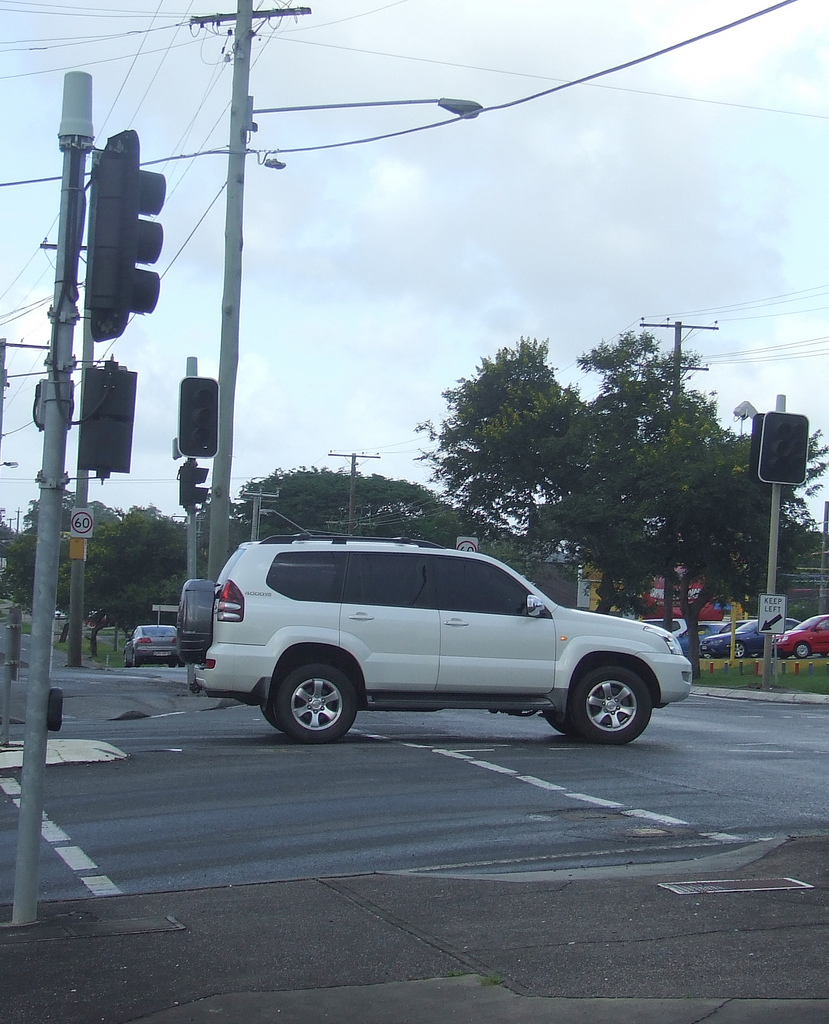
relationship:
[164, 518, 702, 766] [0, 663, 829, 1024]
vehicle at ground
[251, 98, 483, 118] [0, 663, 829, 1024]
light hanging over ground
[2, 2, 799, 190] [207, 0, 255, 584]
wires from pole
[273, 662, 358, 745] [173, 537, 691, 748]
tire on car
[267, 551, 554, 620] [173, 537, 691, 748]
window of car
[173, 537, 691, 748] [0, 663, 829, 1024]
car in middle ground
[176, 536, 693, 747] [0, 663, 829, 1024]
car on ground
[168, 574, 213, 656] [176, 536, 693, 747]
spare tire on car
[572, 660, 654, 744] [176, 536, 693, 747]
tire on car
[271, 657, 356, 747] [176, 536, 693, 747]
tire on car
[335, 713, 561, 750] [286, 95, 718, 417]
shadow under a sky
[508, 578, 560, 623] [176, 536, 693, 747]
view mirror on a car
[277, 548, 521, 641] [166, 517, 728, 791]
window on a suv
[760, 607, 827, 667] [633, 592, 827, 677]
car in a parking lot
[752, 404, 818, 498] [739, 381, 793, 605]
traffic signal on pole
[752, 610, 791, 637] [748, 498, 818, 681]
arrow on pole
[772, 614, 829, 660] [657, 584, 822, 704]
car in parking lot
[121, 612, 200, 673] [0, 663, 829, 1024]
car driving down ground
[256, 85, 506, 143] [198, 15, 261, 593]
light hanging from pole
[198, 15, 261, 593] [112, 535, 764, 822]
pole over cars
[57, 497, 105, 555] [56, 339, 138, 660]
traffic sign on pole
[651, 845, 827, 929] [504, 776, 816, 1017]
sewage drain in sidewalk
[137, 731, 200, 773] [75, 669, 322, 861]
paper lying on ground